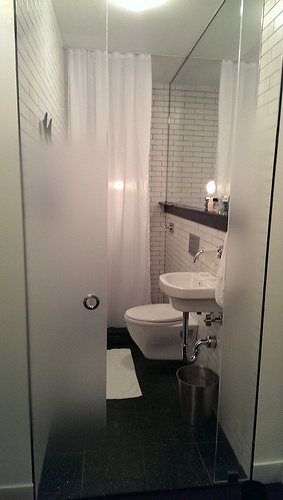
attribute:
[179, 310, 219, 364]
pipe — silver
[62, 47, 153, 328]
curtain — white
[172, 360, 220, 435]
trash — metal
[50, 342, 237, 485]
tiles — black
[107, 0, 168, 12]
light —  on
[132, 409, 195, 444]
tile — speckled, black and white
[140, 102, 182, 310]
brick — white, painted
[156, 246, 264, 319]
sink — white, bathroom sink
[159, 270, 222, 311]
sink — bathroom sink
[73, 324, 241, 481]
ground — tile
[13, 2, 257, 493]
mirror — fogged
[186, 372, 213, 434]
can — silver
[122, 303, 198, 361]
toilet — white, porcelain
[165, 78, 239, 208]
mirror — glass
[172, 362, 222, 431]
trash bin — silver